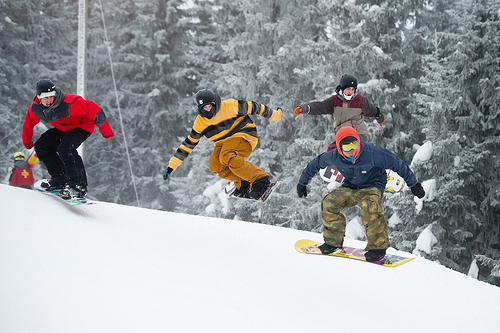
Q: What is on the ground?
A: Snow.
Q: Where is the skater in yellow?
A: Air.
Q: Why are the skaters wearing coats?
A: It is cold.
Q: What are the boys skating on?
A: Snow board.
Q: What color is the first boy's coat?
A: Blue.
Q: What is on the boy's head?
A: Hat.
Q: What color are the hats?
A: Black.